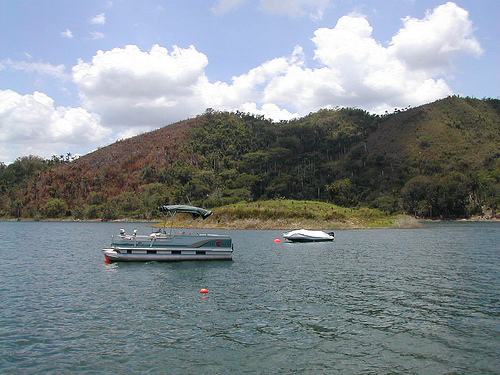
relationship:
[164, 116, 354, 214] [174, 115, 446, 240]
trees in place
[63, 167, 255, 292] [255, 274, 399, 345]
boat in water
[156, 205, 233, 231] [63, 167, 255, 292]
canopy over boat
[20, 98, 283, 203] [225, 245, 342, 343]
hills along water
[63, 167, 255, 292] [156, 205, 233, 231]
boat has canopy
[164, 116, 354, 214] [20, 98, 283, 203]
trees on hills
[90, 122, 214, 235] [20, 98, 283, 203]
grass on hills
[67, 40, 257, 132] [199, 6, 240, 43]
clouds in sky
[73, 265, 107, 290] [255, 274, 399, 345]
edge of water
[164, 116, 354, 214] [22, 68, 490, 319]
trees on island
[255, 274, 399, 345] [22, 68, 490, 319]
water next to island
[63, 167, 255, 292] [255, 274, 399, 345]
ship in water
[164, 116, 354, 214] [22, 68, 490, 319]
trees on top of island